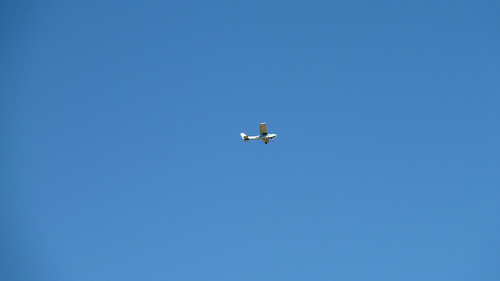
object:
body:
[247, 134, 272, 140]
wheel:
[263, 132, 268, 135]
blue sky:
[0, 0, 500, 281]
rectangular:
[263, 133, 268, 136]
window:
[267, 133, 270, 135]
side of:
[248, 135, 261, 139]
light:
[248, 136, 257, 140]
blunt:
[240, 132, 250, 142]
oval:
[246, 133, 277, 140]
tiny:
[262, 138, 270, 144]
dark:
[244, 136, 249, 138]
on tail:
[240, 132, 247, 139]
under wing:
[260, 130, 268, 141]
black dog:
[243, 136, 250, 143]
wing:
[259, 122, 267, 135]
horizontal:
[236, 121, 294, 153]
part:
[231, 29, 310, 69]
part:
[265, 141, 268, 144]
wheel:
[269, 137, 273, 139]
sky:
[0, 0, 500, 280]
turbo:
[259, 122, 270, 143]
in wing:
[259, 122, 268, 136]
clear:
[0, 0, 500, 281]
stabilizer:
[239, 132, 246, 139]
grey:
[260, 126, 268, 133]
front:
[267, 133, 279, 142]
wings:
[261, 138, 270, 143]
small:
[238, 121, 280, 146]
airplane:
[240, 122, 278, 144]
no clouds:
[153, 26, 390, 108]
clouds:
[219, 13, 350, 99]